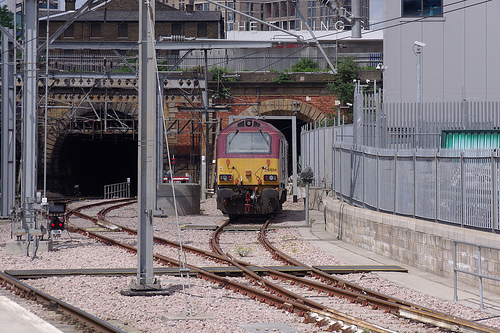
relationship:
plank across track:
[85, 254, 421, 277] [69, 218, 413, 331]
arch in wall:
[242, 97, 333, 141] [26, 75, 336, 200]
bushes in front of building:
[186, 57, 362, 114] [226, 8, 381, 68]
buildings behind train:
[46, 0, 383, 132] [197, 88, 338, 259]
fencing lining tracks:
[294, 82, 489, 238] [60, 199, 452, 331]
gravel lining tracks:
[0, 195, 498, 332] [62, 192, 499, 332]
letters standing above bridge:
[219, 16, 351, 37] [24, 37, 375, 122]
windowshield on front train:
[225, 130, 273, 155] [209, 110, 293, 218]